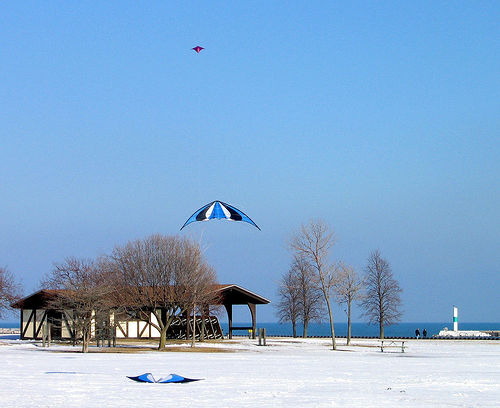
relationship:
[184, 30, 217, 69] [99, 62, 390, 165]
kite in sky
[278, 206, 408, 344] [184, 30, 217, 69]
tree near kite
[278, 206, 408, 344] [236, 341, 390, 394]
tree on ground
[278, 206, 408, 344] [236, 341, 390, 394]
tree in ground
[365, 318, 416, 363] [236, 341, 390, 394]
table on ground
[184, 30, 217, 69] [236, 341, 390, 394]
kite above ground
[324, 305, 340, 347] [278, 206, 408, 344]
stem of tree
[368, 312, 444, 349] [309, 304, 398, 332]
people by water